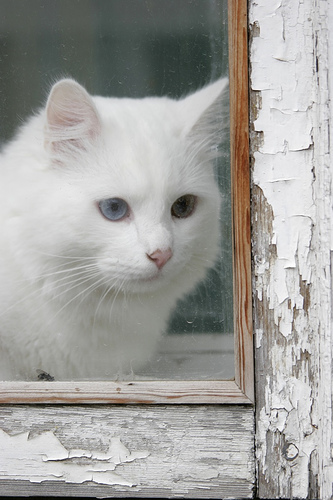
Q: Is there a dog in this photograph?
A: No, there are no dogs.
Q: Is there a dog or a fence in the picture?
A: No, there are no dogs or fences.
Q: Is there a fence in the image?
A: No, there are no fences.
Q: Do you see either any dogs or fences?
A: No, there are no fences or dogs.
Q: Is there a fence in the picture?
A: No, there are no fences.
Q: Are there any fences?
A: No, there are no fences.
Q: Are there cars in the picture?
A: No, there are no cars.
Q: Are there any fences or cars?
A: No, there are no cars or fences.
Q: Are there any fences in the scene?
A: No, there are no fences.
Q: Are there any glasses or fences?
A: No, there are no fences or glasses.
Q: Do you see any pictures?
A: No, there are no pictures.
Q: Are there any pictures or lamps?
A: No, there are no pictures or lamps.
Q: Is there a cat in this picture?
A: Yes, there is a cat.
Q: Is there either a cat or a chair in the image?
A: Yes, there is a cat.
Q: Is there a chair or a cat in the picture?
A: Yes, there is a cat.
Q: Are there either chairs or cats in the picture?
A: Yes, there is a cat.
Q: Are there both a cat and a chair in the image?
A: No, there is a cat but no chairs.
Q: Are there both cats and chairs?
A: No, there is a cat but no chairs.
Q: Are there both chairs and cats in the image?
A: No, there is a cat but no chairs.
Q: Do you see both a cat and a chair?
A: No, there is a cat but no chairs.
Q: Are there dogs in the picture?
A: No, there are no dogs.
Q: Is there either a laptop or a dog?
A: No, there are no dogs or laptops.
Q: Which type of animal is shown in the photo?
A: The animal is a cat.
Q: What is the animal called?
A: The animal is a cat.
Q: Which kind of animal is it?
A: The animal is a cat.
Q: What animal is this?
A: This is a cat.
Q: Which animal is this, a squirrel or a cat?
A: This is a cat.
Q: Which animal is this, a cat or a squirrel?
A: This is a cat.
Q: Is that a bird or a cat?
A: That is a cat.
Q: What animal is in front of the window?
A: The cat is in front of the window.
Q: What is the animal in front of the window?
A: The animal is a cat.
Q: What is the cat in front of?
A: The cat is in front of the window.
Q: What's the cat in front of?
A: The cat is in front of the window.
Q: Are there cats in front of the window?
A: Yes, there is a cat in front of the window.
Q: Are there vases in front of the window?
A: No, there is a cat in front of the window.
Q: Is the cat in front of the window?
A: Yes, the cat is in front of the window.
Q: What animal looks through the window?
A: The cat looks through the window.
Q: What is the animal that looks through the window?
A: The animal is a cat.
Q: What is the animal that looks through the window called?
A: The animal is a cat.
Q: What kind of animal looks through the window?
A: The animal is a cat.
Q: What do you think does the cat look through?
A: The cat looks through the window.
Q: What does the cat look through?
A: The cat looks through the window.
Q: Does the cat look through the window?
A: Yes, the cat looks through the window.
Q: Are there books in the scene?
A: No, there are no books.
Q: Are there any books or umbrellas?
A: No, there are no books or umbrellas.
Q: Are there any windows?
A: Yes, there is a window.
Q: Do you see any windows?
A: Yes, there is a window.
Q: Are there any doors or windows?
A: Yes, there is a window.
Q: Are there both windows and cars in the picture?
A: No, there is a window but no cars.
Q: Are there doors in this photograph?
A: No, there are no doors.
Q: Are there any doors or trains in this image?
A: No, there are no doors or trains.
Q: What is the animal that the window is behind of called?
A: The animal is a cat.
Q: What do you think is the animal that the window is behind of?
A: The animal is a cat.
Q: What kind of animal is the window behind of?
A: The window is behind the cat.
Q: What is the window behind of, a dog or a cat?
A: The window is behind a cat.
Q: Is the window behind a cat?
A: Yes, the window is behind a cat.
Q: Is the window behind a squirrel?
A: No, the window is behind a cat.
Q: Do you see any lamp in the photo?
A: No, there are no lamps.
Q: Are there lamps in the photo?
A: No, there are no lamps.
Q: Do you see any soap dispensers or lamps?
A: No, there are no lamps or soap dispensers.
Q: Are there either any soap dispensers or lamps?
A: No, there are no lamps or soap dispensers.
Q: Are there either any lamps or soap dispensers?
A: No, there are no lamps or soap dispensers.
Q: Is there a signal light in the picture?
A: No, there are no traffic lights.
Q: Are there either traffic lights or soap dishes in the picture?
A: No, there are no traffic lights or soap dishes.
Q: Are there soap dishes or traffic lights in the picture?
A: No, there are no traffic lights or soap dishes.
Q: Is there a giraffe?
A: No, there are no giraffes.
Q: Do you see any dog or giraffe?
A: No, there are no giraffes or dogs.